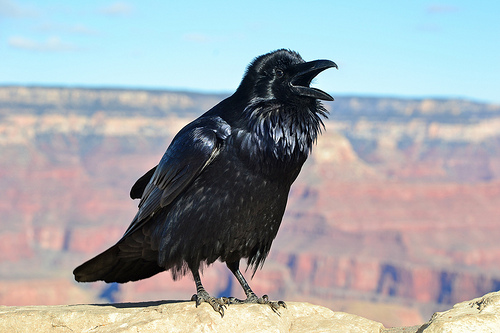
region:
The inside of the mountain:
[352, 114, 478, 283]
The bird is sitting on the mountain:
[58, 43, 351, 318]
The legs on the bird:
[190, 260, 254, 292]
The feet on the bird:
[188, 286, 288, 318]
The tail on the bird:
[71, 229, 161, 291]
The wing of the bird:
[127, 121, 232, 226]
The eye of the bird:
[254, 56, 289, 84]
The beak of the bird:
[285, 55, 342, 102]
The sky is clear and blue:
[62, 20, 242, 57]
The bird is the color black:
[76, 38, 358, 322]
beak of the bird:
[294, 48, 348, 112]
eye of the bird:
[263, 56, 296, 88]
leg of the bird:
[223, 243, 305, 323]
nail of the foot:
[250, 288, 275, 314]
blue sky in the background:
[383, 9, 466, 58]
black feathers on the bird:
[121, 121, 236, 216]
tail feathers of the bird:
[84, 220, 155, 287]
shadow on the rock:
[98, 289, 181, 314]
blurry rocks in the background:
[328, 185, 452, 294]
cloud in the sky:
[7, 20, 67, 67]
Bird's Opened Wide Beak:
[286, 58, 337, 103]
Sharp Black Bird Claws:
[182, 263, 294, 316]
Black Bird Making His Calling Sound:
[75, 49, 338, 315]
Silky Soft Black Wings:
[70, 126, 232, 285]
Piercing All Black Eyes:
[273, 66, 288, 80]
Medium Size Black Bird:
[68, 47, 349, 322]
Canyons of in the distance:
[0, 103, 495, 298]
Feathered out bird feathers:
[246, 98, 343, 157]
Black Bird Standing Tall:
[75, 48, 344, 305]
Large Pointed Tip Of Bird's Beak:
[321, 52, 343, 75]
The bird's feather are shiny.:
[65, 30, 346, 329]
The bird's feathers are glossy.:
[66, 28, 353, 328]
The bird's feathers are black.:
[63, 36, 352, 331]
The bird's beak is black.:
[62, 26, 347, 328]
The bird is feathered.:
[67, 18, 345, 321]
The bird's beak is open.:
[67, 33, 346, 323]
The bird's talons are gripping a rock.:
[57, 28, 356, 331]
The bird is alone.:
[7, 33, 484, 327]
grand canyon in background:
[8, 68, 498, 321]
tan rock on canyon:
[421, 281, 498, 331]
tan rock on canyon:
[7, 295, 382, 326]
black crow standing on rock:
[61, 13, 356, 331]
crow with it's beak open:
[278, 50, 342, 115]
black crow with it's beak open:
[251, 45, 365, 160]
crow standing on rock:
[93, 22, 391, 331]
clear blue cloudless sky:
[101, 18, 179, 61]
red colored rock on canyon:
[338, 152, 472, 279]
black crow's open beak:
[282, 46, 348, 119]